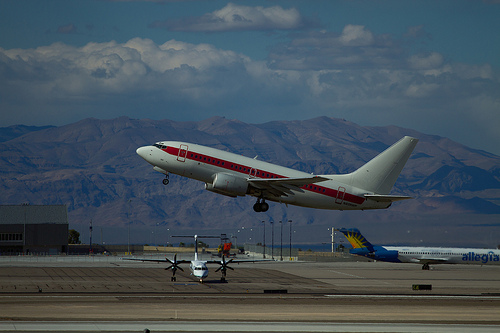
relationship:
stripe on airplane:
[159, 143, 365, 203] [135, 132, 417, 215]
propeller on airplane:
[163, 253, 186, 275] [142, 230, 237, 291]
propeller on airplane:
[213, 253, 236, 275] [142, 230, 237, 291]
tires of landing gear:
[237, 190, 281, 222] [250, 190, 280, 213]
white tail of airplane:
[328, 119, 417, 181] [133, 122, 426, 214]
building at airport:
[0, 205, 70, 255] [0, 186, 499, 329]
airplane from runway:
[135, 132, 417, 215] [0, 295, 500, 330]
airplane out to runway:
[135, 132, 418, 213] [0, 295, 500, 330]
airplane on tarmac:
[331, 222, 499, 268] [262, 260, 498, 290]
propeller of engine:
[213, 253, 236, 275] [221, 260, 229, 270]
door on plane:
[175, 143, 190, 163] [134, 132, 418, 212]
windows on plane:
[187, 150, 254, 178] [140, 115, 429, 220]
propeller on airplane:
[161, 253, 190, 273] [123, 234, 238, 284]